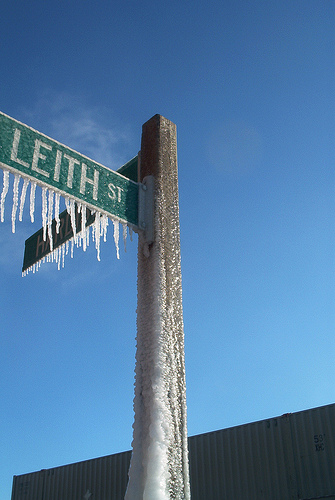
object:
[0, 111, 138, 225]
sign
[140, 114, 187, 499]
pole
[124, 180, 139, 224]
ice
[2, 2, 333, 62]
sky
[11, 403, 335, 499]
building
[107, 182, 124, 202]
st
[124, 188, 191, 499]
ice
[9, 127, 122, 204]
leith st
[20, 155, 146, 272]
sign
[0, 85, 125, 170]
clouds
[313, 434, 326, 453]
writing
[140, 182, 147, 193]
bolts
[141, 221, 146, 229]
screw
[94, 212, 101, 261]
icecle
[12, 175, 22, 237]
icicle